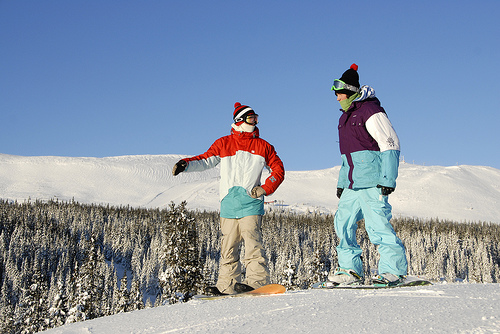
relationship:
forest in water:
[0, 196, 497, 334] [118, 241, 145, 334]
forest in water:
[0, 196, 497, 334] [84, 217, 127, 309]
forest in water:
[0, 196, 497, 334] [104, 220, 147, 316]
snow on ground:
[368, 282, 462, 310] [46, 169, 148, 216]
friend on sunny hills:
[172, 101, 286, 295] [0, 154, 500, 227]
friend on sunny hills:
[328, 62, 408, 284] [0, 154, 500, 227]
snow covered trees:
[41, 158, 186, 196] [26, 264, 66, 331]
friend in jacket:
[172, 101, 286, 295] [337, 97, 399, 190]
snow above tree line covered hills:
[50, 158, 146, 219] [0, 154, 500, 227]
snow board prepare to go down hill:
[308, 275, 433, 287] [31, 282, 500, 334]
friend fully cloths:
[172, 101, 286, 295] [220, 135, 399, 246]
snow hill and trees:
[60, 248, 209, 334] [57, 216, 117, 292]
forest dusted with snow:
[3, 200, 498, 312] [5, 155, 497, 222]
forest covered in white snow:
[0, 196, 497, 334] [59, 297, 83, 313]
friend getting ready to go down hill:
[171, 104, 283, 295] [28, 282, 498, 332]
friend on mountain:
[328, 62, 408, 284] [24, 101, 496, 301]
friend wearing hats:
[172, 101, 286, 295] [226, 55, 366, 124]